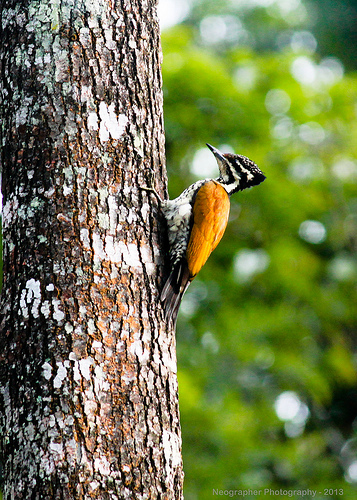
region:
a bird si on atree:
[96, 146, 284, 374]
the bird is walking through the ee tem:
[134, 137, 259, 359]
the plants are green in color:
[259, 84, 352, 321]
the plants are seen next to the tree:
[244, 224, 325, 444]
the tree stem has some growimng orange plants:
[35, 190, 171, 468]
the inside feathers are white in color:
[157, 185, 197, 245]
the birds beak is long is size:
[201, 130, 224, 166]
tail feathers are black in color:
[157, 263, 202, 334]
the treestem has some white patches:
[76, 96, 201, 204]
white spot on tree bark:
[68, 361, 81, 383]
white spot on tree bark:
[50, 359, 66, 391]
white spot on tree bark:
[37, 360, 52, 381]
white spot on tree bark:
[0, 384, 14, 404]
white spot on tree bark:
[50, 296, 65, 327]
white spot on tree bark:
[40, 302, 51, 318]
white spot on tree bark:
[23, 276, 44, 320]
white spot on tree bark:
[17, 286, 30, 320]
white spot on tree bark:
[77, 303, 90, 315]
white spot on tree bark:
[83, 315, 96, 339]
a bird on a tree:
[128, 115, 281, 328]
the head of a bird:
[211, 124, 282, 211]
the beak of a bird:
[195, 140, 220, 162]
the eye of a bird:
[219, 151, 244, 165]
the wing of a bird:
[186, 185, 231, 270]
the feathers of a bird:
[163, 190, 187, 227]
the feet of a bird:
[121, 159, 174, 207]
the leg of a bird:
[148, 184, 166, 208]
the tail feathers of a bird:
[159, 249, 199, 311]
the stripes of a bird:
[219, 164, 250, 192]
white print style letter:
[211, 485, 222, 496]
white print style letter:
[217, 487, 221, 497]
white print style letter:
[222, 487, 228, 496]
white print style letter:
[227, 488, 235, 498]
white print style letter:
[232, 487, 239, 496]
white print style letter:
[236, 488, 242, 496]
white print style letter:
[240, 487, 249, 496]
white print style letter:
[248, 484, 255, 496]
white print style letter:
[260, 482, 269, 496]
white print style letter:
[286, 488, 293, 497]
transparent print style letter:
[211, 486, 220, 498]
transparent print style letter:
[218, 490, 224, 497]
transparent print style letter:
[223, 488, 229, 496]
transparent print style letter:
[227, 488, 234, 499]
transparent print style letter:
[233, 487, 239, 495]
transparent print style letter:
[235, 487, 242, 495]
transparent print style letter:
[241, 488, 247, 498]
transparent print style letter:
[247, 485, 254, 497]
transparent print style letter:
[262, 485, 268, 496]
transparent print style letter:
[273, 489, 280, 495]